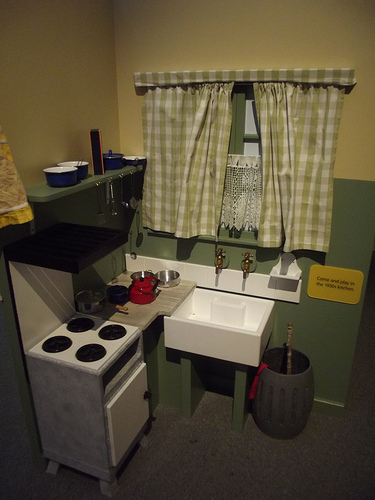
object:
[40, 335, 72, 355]
burner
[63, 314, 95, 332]
burner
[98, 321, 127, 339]
burner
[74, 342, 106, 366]
burner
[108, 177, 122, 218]
utensil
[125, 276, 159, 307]
pot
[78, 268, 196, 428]
table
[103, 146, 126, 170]
pot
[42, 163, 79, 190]
pot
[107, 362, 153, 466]
white door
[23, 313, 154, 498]
stove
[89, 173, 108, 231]
spatula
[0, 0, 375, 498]
kitchen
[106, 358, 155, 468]
cabinet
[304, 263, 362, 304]
wood railing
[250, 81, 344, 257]
curtains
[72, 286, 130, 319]
pan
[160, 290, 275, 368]
sink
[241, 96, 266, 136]
window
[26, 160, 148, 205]
shelf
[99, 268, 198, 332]
counter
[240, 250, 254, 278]
faucets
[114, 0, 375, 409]
wall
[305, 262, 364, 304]
sign